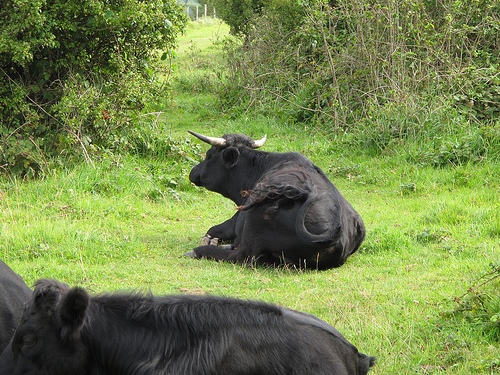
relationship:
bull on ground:
[187, 129, 366, 270] [2, 22, 499, 373]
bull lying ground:
[1, 258, 373, 369] [2, 22, 499, 373]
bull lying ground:
[1, 255, 35, 359] [2, 22, 499, 373]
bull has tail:
[187, 129, 366, 270] [247, 182, 342, 245]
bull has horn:
[187, 129, 366, 270] [188, 130, 226, 145]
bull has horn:
[187, 129, 366, 270] [254, 132, 266, 145]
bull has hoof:
[187, 129, 366, 270] [200, 234, 218, 246]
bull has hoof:
[187, 129, 366, 270] [186, 250, 196, 258]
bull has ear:
[187, 129, 366, 270] [222, 147, 240, 171]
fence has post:
[184, 4, 227, 21] [204, 4, 207, 17]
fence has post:
[184, 4, 227, 21] [195, 4, 200, 17]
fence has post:
[184, 4, 227, 21] [213, 5, 218, 15]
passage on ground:
[128, 53, 302, 138] [2, 22, 499, 373]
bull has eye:
[1, 258, 373, 369] [23, 334, 35, 344]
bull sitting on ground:
[187, 129, 366, 270] [2, 22, 499, 373]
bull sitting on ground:
[1, 258, 373, 369] [2, 22, 499, 373]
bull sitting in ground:
[187, 129, 366, 270] [2, 22, 499, 373]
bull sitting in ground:
[1, 258, 373, 369] [2, 22, 499, 373]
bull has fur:
[187, 129, 366, 270] [184, 137, 364, 264]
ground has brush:
[2, 22, 499, 373] [1, 0, 180, 182]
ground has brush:
[2, 22, 499, 373] [223, 3, 499, 140]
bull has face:
[187, 129, 366, 270] [189, 147, 217, 188]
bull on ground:
[1, 258, 373, 369] [2, 22, 499, 373]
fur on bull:
[184, 137, 364, 264] [187, 129, 366, 270]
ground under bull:
[2, 22, 499, 373] [187, 129, 366, 270]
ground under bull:
[2, 22, 499, 373] [1, 258, 373, 369]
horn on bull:
[188, 130, 226, 145] [187, 129, 366, 270]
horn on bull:
[254, 132, 266, 145] [187, 129, 366, 270]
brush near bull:
[1, 0, 180, 182] [187, 129, 366, 270]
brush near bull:
[223, 3, 499, 140] [187, 129, 366, 270]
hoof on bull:
[200, 234, 218, 246] [187, 129, 366, 270]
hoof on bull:
[186, 250, 196, 258] [187, 129, 366, 270]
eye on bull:
[23, 334, 35, 344] [1, 258, 373, 369]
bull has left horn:
[187, 129, 366, 270] [188, 130, 226, 145]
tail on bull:
[247, 182, 342, 245] [187, 129, 366, 270]